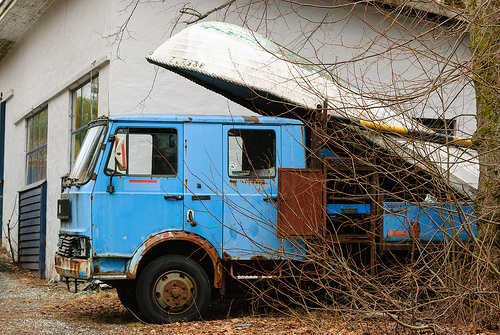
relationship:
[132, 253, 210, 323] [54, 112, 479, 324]
wheel of blue truck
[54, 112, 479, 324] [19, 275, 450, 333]
blue truck sitting on ground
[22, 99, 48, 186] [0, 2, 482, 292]
window on building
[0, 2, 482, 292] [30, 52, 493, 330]
building next to truck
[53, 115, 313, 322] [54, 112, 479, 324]
cab of blue truck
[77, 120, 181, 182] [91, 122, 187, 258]
window on blue door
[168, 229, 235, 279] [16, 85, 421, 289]
rust on side of truck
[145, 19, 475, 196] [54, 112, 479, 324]
boat in back of blue truck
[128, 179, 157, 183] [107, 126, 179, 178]
red stripe under window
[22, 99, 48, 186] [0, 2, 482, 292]
window in building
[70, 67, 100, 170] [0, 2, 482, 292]
window in building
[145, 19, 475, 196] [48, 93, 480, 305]
boat upside down on truck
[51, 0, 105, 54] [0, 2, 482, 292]
walls of building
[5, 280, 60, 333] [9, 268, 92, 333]
gravel of driveway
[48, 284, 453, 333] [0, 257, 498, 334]
leaves on ground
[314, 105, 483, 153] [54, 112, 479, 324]
pole on blue truck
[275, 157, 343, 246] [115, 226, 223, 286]
rust around wheel well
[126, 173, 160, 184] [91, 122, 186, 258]
red stripe on blue door